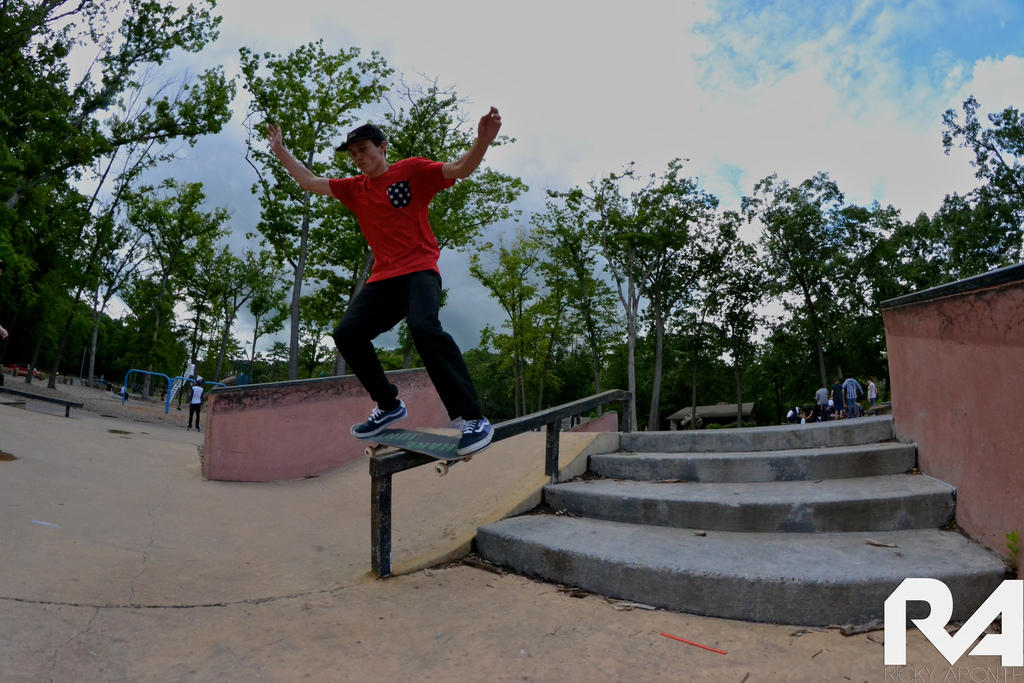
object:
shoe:
[351, 398, 408, 438]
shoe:
[457, 416, 495, 455]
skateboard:
[350, 422, 493, 477]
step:
[469, 509, 1013, 627]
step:
[540, 473, 957, 534]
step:
[586, 441, 915, 483]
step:
[619, 414, 895, 451]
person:
[184, 382, 206, 432]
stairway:
[477, 416, 1021, 637]